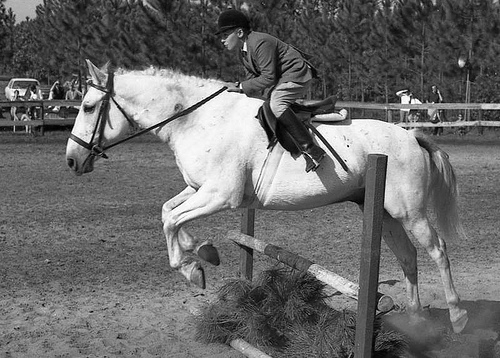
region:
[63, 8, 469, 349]
a girl on a white horse going over a jump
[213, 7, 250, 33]
black riding helmet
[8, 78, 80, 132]
spectators behind fence near horses face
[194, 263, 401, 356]
brush underneath fence jump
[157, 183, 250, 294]
bent front legs of horse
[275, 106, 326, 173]
black boot in stirrup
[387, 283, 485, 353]
dust in air from horses hooves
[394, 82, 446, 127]
spectators behind fence near horses tail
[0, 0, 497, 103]
trees behind fence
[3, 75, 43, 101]
white car behind fence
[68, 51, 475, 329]
shite horse is building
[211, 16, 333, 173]
jockey on white horse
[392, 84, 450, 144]
Horse and rider on side of fence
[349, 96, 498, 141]
wooden fence around field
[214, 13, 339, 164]
rider in saddle on horse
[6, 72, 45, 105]
white car parked in front of fence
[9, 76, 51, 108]
white car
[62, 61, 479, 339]
Horse in motion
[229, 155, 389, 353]
horse jumping wooden fence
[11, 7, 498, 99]
trees in on other side of fence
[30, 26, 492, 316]
Horse jumping over pole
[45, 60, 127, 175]
The horse has a halter on its face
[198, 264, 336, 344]
Clump of grass by jump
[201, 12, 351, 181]
Jockey on top of the horse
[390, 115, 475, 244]
Long tail on the horse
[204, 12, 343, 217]
The jockey is leaning forward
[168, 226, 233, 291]
Horse has two front hooves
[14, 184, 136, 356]
The dirt has tracks on it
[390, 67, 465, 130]
People outside the fence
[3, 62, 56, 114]
White car parked in lot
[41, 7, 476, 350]
a woman jumping a horse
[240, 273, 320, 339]
a spiny plant on the ground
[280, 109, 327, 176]
a black shiny boot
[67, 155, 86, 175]
a large nostril on a snout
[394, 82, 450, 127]
people watching from afar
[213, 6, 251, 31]
a black helmet on a head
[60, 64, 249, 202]
a powerful white stallion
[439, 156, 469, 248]
a long white tail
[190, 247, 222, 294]
sturdy black hooves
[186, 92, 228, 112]
a long back strap on the reign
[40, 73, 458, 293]
a white horse jumping a obsticle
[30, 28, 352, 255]
a woman riding a horse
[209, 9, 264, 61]
a woman wearing a black hat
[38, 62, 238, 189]
a horse wearing a bridle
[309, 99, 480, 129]
a wooden fence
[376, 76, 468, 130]
people standing near a fence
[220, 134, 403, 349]
a wooden obsticle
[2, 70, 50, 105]
a white car parked in a field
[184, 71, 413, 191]
a horse with a saddle on it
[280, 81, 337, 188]
a woman wearing black boots